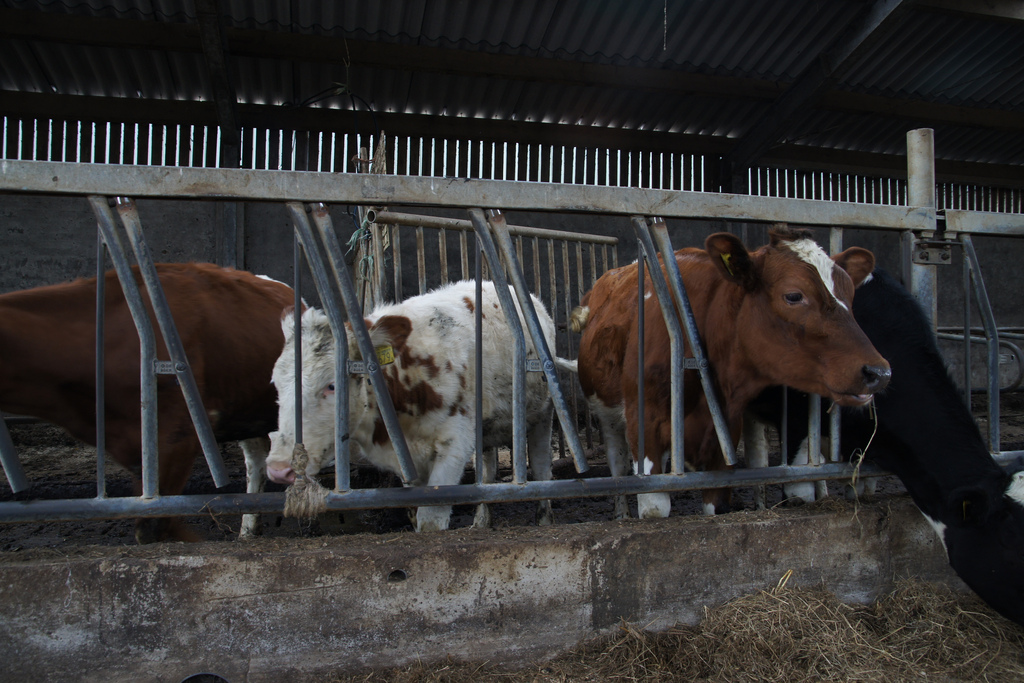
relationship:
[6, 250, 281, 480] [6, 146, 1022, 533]
cow behind fence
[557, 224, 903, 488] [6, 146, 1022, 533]
cow behind fence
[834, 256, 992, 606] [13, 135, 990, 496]
cow standing behind fence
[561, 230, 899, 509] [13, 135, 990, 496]
cow standing behind fence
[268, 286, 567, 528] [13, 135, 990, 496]
cow standing behind fence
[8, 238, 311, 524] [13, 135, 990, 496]
cow standing behind fence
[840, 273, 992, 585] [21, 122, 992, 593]
cow in cage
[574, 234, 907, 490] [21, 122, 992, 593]
cow in cage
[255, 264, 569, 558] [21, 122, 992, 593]
cow in cage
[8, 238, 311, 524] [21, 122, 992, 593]
cow in cage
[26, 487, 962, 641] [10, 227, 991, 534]
barrier by cows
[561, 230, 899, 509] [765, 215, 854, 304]
cow has a white spot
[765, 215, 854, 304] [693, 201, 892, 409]
spot on head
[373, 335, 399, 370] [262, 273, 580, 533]
tag on cow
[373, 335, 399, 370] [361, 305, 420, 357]
tag on ear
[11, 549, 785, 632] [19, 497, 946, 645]
surface of concrete wall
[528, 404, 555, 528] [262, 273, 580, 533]
leg belonging to cow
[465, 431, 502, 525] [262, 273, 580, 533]
leg belonging to cow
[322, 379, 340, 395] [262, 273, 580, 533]
eye belonging to cow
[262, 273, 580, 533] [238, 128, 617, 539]
cow standing in middle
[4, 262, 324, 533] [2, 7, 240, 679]
cow to left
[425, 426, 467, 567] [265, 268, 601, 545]
leg of cow